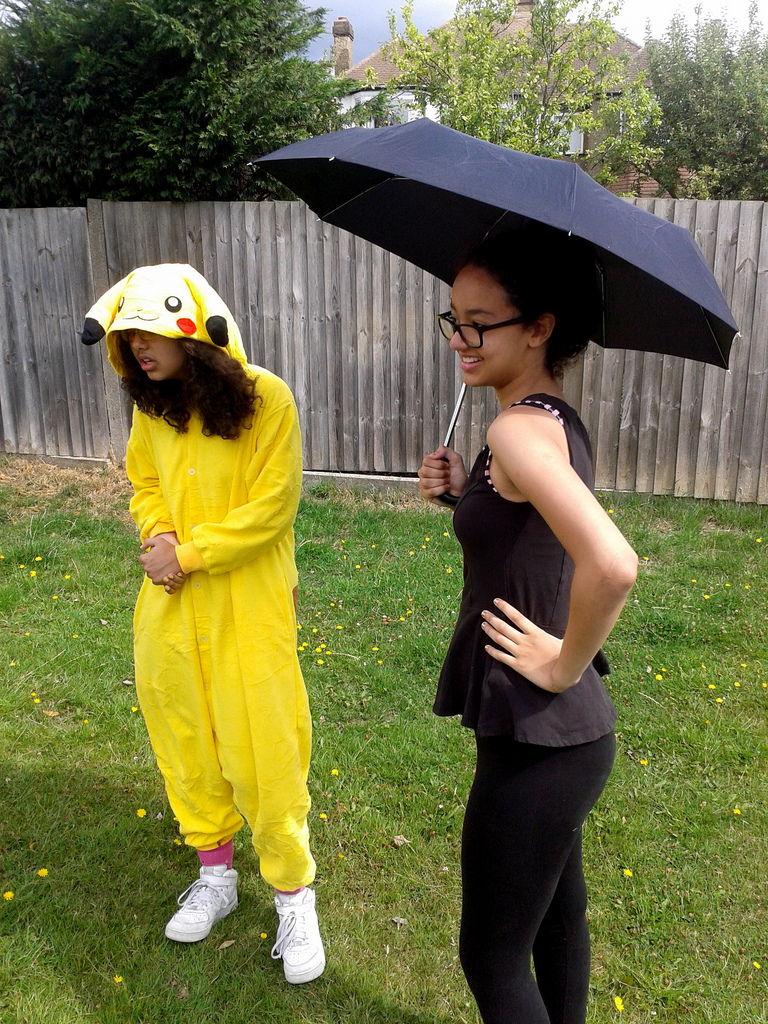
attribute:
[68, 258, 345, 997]
adult — in yellow, young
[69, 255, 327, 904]
pjs — pokemon, pikachu, yellow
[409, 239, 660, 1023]
girl — in black, smiling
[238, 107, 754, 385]
umbrella — black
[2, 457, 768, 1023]
grass — green, low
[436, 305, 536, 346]
glasses — black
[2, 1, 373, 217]
tree — green, dark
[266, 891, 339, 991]
shoes — white, tennis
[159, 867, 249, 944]
shoes — white, tennis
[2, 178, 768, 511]
fence — wooden, wood, grey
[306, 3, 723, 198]
house — background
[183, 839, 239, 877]
socks — pink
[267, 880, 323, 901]
socks — pink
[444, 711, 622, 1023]
tights — black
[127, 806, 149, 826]
flowers — yellow